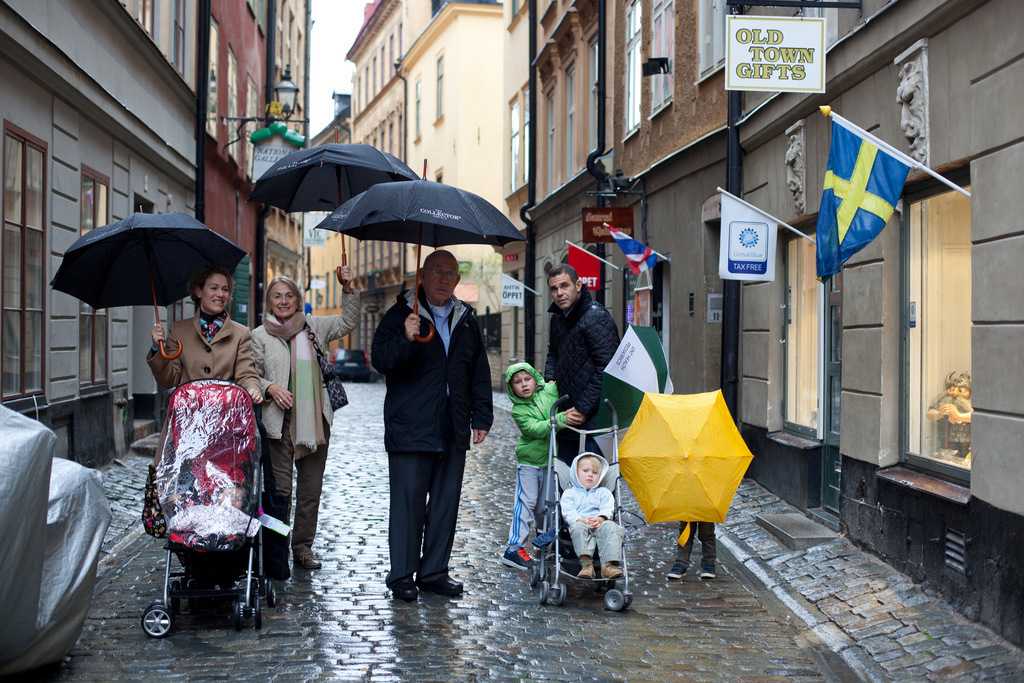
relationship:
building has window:
[702, 4, 1022, 640] [888, 160, 988, 487]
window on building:
[639, 1, 691, 133] [512, 5, 992, 621]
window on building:
[69, 170, 121, 382] [9, 13, 318, 482]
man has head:
[359, 239, 507, 611] [411, 235, 470, 313]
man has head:
[534, 254, 634, 447] [538, 257, 582, 316]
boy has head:
[549, 432, 638, 595] [572, 447, 601, 491]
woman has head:
[143, 254, 254, 388] [188, 250, 247, 324]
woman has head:
[244, 261, 359, 599] [255, 276, 314, 328]